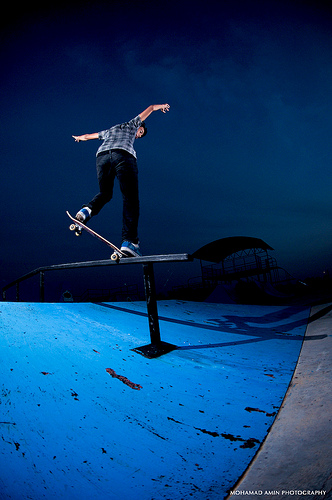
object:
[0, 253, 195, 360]
railing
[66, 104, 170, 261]
skater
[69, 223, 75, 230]
wheel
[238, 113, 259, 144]
ground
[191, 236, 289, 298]
structure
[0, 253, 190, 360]
rail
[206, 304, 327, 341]
shadow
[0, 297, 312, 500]
blue ramp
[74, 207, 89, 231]
shoe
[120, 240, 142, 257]
shoe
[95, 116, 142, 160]
plaid shirt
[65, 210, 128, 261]
skateboard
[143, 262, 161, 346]
pole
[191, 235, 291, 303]
shed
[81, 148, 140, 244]
pants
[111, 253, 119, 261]
wheel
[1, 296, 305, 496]
ramp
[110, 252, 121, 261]
wheel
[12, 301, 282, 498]
ground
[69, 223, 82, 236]
wheels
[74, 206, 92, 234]
foot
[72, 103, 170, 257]
boy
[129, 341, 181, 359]
base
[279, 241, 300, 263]
background